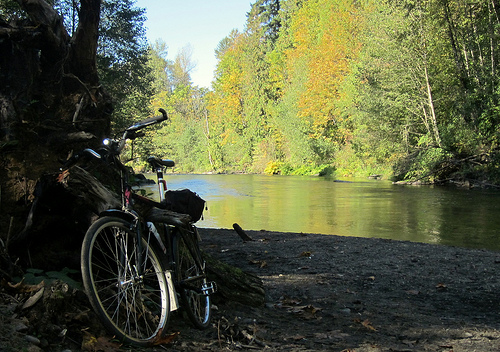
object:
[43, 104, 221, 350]
bike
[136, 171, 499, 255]
lake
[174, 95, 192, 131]
trees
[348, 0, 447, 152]
tree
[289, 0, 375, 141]
tree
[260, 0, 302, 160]
tree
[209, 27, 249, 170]
tree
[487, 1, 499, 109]
tree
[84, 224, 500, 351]
bank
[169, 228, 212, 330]
tire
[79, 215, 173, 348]
tire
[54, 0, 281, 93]
sky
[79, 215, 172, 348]
wheel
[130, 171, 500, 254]
water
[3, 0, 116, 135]
tree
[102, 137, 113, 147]
bell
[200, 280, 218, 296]
pedal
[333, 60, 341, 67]
leaves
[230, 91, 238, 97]
leaves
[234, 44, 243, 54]
leaves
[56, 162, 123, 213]
trunk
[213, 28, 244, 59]
treetop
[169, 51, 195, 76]
treetop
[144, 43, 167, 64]
treetop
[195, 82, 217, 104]
treetop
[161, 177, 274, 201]
reflection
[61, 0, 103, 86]
trunk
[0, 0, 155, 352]
hill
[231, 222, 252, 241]
tree stump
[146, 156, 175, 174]
seat